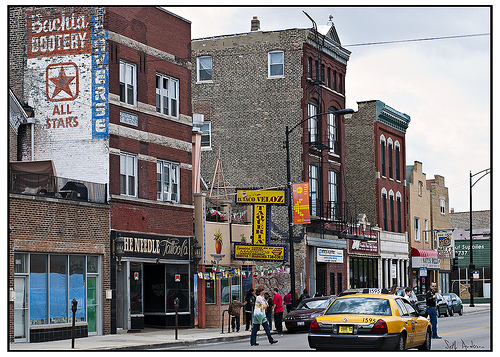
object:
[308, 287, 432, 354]
taxicab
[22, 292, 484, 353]
street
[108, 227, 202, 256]
restaurant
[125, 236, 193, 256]
advertising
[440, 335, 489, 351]
signature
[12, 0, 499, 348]
photo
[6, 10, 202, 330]
building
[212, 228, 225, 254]
pineapple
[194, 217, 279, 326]
restaurant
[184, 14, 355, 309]
building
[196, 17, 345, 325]
brick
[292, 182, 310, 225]
banner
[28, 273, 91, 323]
tarp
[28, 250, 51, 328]
window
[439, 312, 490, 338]
line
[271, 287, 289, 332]
man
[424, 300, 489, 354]
road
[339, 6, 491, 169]
sky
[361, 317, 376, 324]
1595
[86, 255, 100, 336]
window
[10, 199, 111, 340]
store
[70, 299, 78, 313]
head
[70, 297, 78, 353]
meter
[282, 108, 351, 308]
lamp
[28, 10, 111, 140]
sign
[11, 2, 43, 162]
wall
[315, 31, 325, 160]
escape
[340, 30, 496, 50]
wire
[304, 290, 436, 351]
cab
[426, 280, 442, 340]
man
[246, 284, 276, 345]
woman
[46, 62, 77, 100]
star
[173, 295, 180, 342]
meter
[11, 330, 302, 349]
sidewalk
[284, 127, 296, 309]
pole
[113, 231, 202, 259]
sign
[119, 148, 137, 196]
window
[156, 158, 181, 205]
window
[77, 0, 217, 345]
store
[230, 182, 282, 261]
sign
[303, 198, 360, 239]
ladder